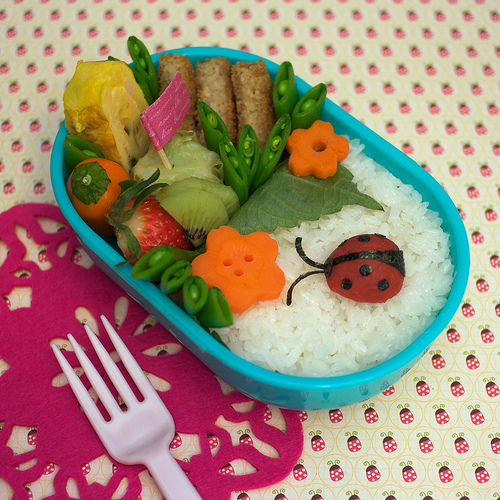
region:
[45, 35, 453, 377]
the food in the blue container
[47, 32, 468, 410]
the blue container with the food in it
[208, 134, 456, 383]
the rice in the bowl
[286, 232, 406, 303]
the food shaped like a ladybug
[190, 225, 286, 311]
the carrot shaped like a flower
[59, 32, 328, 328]
the green beans in the container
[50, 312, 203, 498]
the white plastic fork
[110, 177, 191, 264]
the strawberry in the container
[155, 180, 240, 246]
the sliced kiwi in the container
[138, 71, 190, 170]
the pink flag attached to the toothpick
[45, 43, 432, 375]
Food on the bowl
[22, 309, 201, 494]
Fork in the photo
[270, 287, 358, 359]
Rice in the photo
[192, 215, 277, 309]
Carrot slice in the photo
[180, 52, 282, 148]
Kebabs on the bowl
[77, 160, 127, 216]
Carrot in the photo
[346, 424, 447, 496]
Table in the photo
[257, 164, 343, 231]
Kales in the photo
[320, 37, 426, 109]
Table cloth in the photo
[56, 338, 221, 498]
A plastic fork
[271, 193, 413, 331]
White rice in the bowl.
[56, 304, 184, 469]
A white plastic fork next to th bowl.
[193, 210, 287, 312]
A carrot shaped like a star fish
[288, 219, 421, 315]
A ladybug on top of the rice.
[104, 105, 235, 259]
Fruits and vegetables in the blue container.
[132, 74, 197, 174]
A flag on the toothpick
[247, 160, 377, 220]
Green leaf on top of the rice.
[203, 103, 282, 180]
Green string beans in the bowl.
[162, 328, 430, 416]
The bowl is blue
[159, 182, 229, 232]
Kiwi next to the strawberry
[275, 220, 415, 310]
Tomato disguised as ladybug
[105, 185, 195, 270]
Red ripe strawberry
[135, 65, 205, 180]
Pink toothpick flag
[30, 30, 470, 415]
Fruits and vegetables with rice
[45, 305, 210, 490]
White plastic disposable fork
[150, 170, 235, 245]
Two slices of Kiwi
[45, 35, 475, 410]
Blue bowl filled with rice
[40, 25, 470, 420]
Green peas with rice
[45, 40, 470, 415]
Blue plastic bowl filled with white rice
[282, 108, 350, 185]
Star shaped orange vegetable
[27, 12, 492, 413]
this is a plate of food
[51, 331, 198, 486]
this is a fork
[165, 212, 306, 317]
this is a slice of carrot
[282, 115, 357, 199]
this is a slice of carrot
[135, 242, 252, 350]
these are french beans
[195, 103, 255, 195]
these are french beans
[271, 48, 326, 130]
these are french beans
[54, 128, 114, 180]
these are french beans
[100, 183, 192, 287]
this is a red berry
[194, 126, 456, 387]
this is white rice